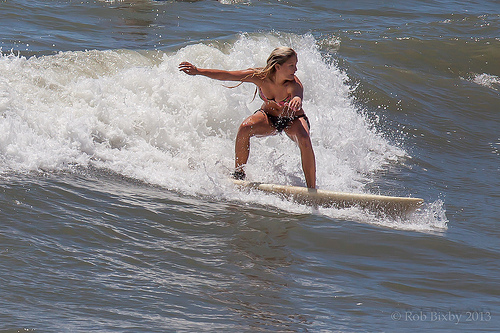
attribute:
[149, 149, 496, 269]
short surfboard — white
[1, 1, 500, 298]
wate — grayish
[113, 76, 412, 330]
wave — big